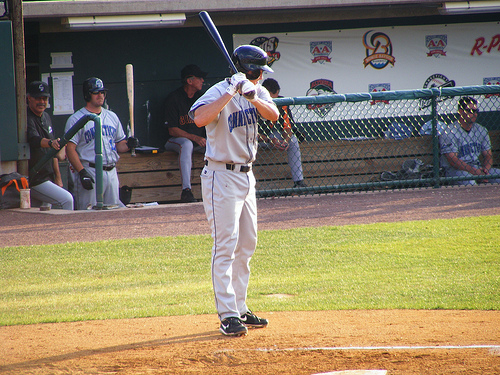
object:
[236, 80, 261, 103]
glove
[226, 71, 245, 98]
batter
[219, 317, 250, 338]
shoe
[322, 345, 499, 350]
line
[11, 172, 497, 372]
field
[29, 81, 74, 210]
man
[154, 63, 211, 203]
man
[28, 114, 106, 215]
green rail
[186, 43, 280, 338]
baseball player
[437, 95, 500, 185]
baseball player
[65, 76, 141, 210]
baseball player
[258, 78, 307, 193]
baseball player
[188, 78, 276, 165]
baseball jersey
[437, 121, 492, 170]
baseball jersey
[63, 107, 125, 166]
baseball jersey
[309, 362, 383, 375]
home plate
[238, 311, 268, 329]
shoe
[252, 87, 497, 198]
dugout railing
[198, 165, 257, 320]
gray pants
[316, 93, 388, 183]
fence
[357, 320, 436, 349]
dirt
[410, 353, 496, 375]
dirt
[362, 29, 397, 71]
logo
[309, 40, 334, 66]
logo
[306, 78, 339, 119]
logo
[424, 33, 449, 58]
logo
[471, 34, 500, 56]
logo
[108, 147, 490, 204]
dugout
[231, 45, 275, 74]
helmet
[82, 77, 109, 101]
helmet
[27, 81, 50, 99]
cap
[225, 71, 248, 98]
glove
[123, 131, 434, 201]
bench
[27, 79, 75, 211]
coach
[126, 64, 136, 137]
bat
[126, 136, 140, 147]
hand